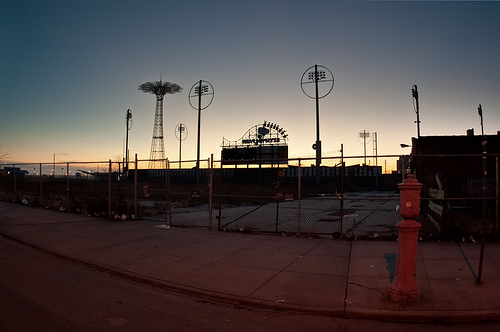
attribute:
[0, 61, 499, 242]
amusement park — fenced-off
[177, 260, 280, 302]
square — cement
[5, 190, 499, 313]
sidewalk — empty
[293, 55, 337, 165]
structure — circular, metal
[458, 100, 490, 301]
pole — black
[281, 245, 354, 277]
square — cement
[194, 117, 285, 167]
sign — curvy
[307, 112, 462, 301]
hydrant — red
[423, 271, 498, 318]
square — cement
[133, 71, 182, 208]
tower — tall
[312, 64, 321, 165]
pole — tall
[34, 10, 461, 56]
sky — clear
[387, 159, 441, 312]
hydrant — red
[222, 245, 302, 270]
square — cement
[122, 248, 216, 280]
square — cement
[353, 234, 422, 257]
square — cement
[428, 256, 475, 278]
square — cement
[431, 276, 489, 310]
square — cement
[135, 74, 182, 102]
top — circular